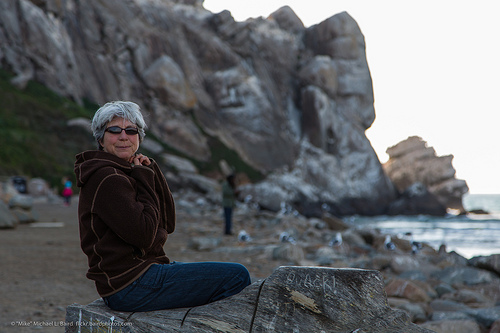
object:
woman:
[73, 100, 252, 312]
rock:
[65, 265, 437, 332]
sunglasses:
[104, 126, 138, 135]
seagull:
[383, 235, 402, 257]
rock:
[370, 255, 392, 271]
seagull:
[410, 240, 421, 255]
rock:
[391, 255, 420, 273]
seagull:
[328, 232, 343, 249]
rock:
[313, 246, 335, 266]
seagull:
[278, 231, 295, 246]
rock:
[269, 245, 293, 261]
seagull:
[234, 229, 253, 244]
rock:
[245, 238, 256, 245]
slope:
[0, 57, 267, 213]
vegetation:
[0, 57, 266, 197]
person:
[218, 173, 247, 236]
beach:
[1, 200, 500, 332]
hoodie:
[73, 150, 176, 297]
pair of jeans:
[102, 261, 251, 312]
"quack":
[285, 273, 332, 293]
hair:
[90, 100, 149, 149]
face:
[104, 117, 140, 159]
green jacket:
[218, 182, 237, 208]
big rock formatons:
[382, 135, 469, 217]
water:
[339, 194, 500, 260]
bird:
[383, 235, 397, 253]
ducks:
[236, 229, 422, 255]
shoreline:
[312, 207, 500, 332]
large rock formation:
[0, 0, 394, 218]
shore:
[339, 214, 500, 260]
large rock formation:
[384, 135, 472, 219]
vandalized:
[283, 287, 321, 315]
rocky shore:
[189, 211, 500, 287]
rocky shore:
[63, 236, 500, 333]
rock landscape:
[1, 0, 472, 217]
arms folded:
[93, 153, 176, 248]